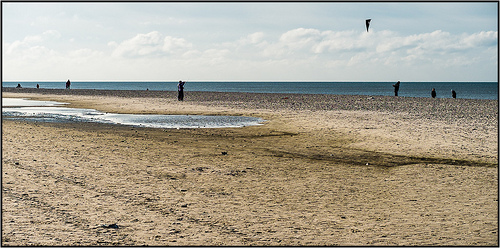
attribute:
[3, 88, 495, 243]
beach — large, sandy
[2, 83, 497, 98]
ocean waters — calm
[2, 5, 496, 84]
clouds — white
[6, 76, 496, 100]
water — blue, strip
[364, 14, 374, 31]
kite — small, black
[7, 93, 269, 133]
puddles — large, silver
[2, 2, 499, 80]
sky — light blue, blue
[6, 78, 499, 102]
water — blue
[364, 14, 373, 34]
kite — airborne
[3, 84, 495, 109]
shoreline — daytime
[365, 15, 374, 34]
kite — airborne